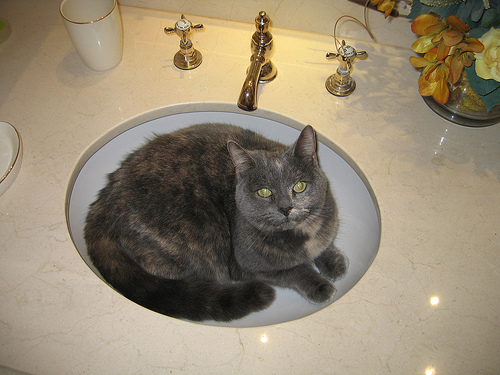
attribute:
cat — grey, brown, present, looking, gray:
[85, 120, 351, 322]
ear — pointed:
[290, 124, 319, 163]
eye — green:
[255, 187, 272, 198]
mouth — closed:
[269, 218, 308, 225]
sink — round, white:
[63, 99, 384, 331]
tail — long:
[84, 225, 273, 323]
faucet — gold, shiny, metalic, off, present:
[237, 9, 280, 112]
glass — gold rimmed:
[58, 0, 126, 75]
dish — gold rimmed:
[0, 118, 23, 190]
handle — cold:
[163, 12, 206, 71]